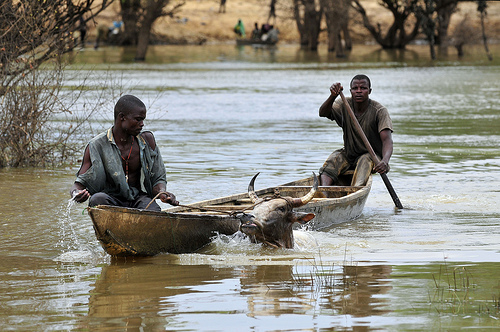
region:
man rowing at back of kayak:
[313, 68, 405, 217]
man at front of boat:
[59, 92, 182, 235]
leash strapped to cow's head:
[137, 190, 289, 221]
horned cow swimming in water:
[234, 166, 321, 255]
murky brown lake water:
[8, 249, 290, 330]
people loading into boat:
[231, 17, 281, 49]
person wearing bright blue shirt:
[112, 14, 126, 38]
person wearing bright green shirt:
[231, 17, 245, 41]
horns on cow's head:
[246, 168, 323, 205]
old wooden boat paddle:
[335, 85, 414, 218]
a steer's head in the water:
[228, 166, 330, 259]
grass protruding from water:
[420, 256, 498, 322]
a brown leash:
[133, 187, 241, 222]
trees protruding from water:
[113, 1, 177, 61]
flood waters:
[0, 37, 497, 329]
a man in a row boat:
[314, 71, 398, 192]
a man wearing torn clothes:
[69, 89, 181, 223]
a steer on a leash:
[230, 166, 325, 256]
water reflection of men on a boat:
[57, 240, 407, 330]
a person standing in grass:
[209, 0, 230, 16]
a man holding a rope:
[68, 94, 184, 229]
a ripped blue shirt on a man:
[77, 130, 177, 211]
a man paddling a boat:
[306, 72, 403, 198]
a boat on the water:
[80, 139, 392, 273]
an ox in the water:
[220, 159, 340, 265]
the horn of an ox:
[285, 167, 322, 212]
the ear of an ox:
[282, 207, 316, 230]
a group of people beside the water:
[232, 15, 282, 48]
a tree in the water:
[128, 3, 173, 67]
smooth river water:
[8, 56, 494, 325]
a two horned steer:
[235, 166, 325, 248]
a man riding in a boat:
[67, 95, 177, 218]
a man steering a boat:
[314, 71, 407, 221]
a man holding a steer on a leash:
[65, 89, 325, 264]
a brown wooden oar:
[333, 84, 406, 221]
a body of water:
[4, 63, 497, 326]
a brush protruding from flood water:
[0, 51, 97, 167]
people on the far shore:
[224, 15, 279, 47]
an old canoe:
[76, 152, 385, 260]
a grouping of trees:
[283, 1, 498, 64]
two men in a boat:
[63, 55, 405, 256]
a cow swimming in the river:
[233, 164, 318, 253]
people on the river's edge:
[228, 17, 292, 55]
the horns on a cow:
[243, 160, 330, 209]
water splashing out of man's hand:
[46, 166, 104, 266]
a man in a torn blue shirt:
[70, 90, 180, 240]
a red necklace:
[115, 142, 140, 192]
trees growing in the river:
[0, 0, 87, 171]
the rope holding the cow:
[157, 188, 228, 225]